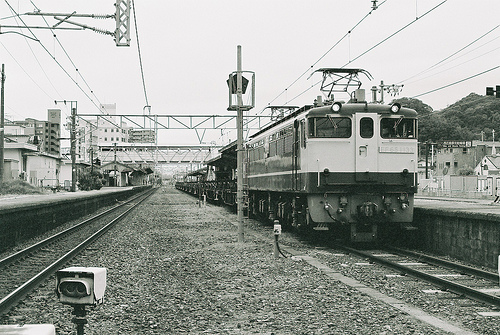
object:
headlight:
[332, 104, 340, 111]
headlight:
[391, 105, 399, 112]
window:
[381, 117, 416, 140]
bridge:
[91, 143, 229, 165]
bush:
[78, 170, 104, 191]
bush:
[1, 180, 48, 195]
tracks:
[0, 188, 157, 312]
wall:
[0, 186, 147, 241]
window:
[308, 116, 354, 139]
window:
[360, 117, 376, 139]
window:
[253, 148, 260, 161]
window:
[269, 142, 277, 157]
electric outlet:
[273, 224, 282, 235]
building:
[3, 119, 63, 191]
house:
[469, 154, 500, 191]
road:
[412, 189, 498, 221]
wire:
[131, 0, 148, 106]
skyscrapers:
[99, 102, 118, 126]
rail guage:
[330, 240, 500, 304]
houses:
[1, 135, 39, 185]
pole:
[235, 43, 245, 241]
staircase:
[243, 160, 250, 220]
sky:
[0, 1, 500, 143]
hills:
[439, 92, 499, 136]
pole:
[273, 221, 280, 259]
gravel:
[252, 288, 255, 290]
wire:
[267, 11, 367, 106]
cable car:
[195, 99, 423, 248]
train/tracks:
[188, 97, 500, 305]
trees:
[417, 111, 468, 177]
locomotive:
[292, 90, 422, 246]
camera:
[54, 266, 109, 307]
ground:
[13, 183, 499, 335]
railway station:
[0, 170, 500, 335]